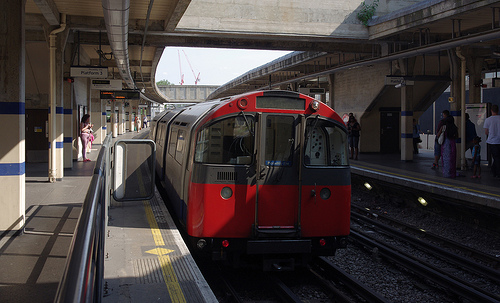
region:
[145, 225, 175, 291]
yellow paint on platform.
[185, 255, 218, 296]
white paint on platform.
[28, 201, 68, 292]
shadows on the platform.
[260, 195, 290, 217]
red paint on the train.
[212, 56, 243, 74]
open sky above platform.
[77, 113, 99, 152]
woman standing on platform.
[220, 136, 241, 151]
windows on the train.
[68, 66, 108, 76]
sign above woman on platform.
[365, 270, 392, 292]
pebbles between the tracks.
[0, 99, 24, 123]
blue paint on the pillar.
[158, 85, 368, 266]
red and black train pulling into the station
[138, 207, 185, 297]
yellow line on the train platform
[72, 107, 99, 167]
lady waiting for her train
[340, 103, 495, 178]
people waiting on the train platform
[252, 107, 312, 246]
back door to the train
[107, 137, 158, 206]
mirror on the side of the train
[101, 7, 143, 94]
silver tubing on the roof of a station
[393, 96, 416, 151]
blue stripes on the train station posts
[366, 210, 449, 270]
railroad tracks on ground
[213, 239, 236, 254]
red light on the back of the train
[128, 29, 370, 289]
the train is red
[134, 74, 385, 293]
the train is red and black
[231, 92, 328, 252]
the train has a door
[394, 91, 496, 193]
people on the walkway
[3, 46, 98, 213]
the pillars have blue stripes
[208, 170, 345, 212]
the train has lights beside the door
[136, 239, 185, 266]
the diamond on the ground is yellow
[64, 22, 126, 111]
a sign is hanging from the ceiling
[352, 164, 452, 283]
two lights beside the train tracks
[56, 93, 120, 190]
a woman is standing alone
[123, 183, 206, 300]
a yellow line on the ground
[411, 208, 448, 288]
The rail road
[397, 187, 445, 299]
The rail road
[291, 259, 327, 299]
The rail road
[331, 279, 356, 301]
The rail road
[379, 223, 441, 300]
The rail road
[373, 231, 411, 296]
The rail road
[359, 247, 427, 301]
The rail road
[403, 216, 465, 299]
The rail road